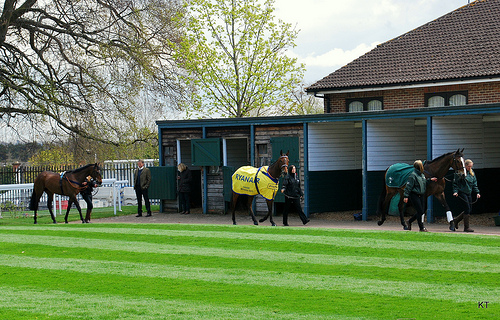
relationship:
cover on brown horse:
[231, 164, 281, 201] [232, 149, 290, 226]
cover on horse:
[385, 157, 418, 189] [376, 145, 466, 230]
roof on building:
[346, 6, 497, 78] [155, 0, 500, 217]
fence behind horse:
[1, 160, 161, 213] [23, 157, 106, 227]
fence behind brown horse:
[1, 160, 161, 213] [232, 149, 290, 226]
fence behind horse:
[1, 160, 161, 213] [376, 147, 470, 237]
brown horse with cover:
[222, 147, 294, 229] [231, 165, 280, 200]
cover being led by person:
[231, 165, 280, 200] [281, 165, 311, 226]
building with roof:
[151, 0, 499, 232] [303, 0, 500, 79]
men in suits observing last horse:
[131, 154, 196, 218] [23, 157, 106, 227]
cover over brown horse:
[231, 164, 281, 201] [232, 149, 290, 226]